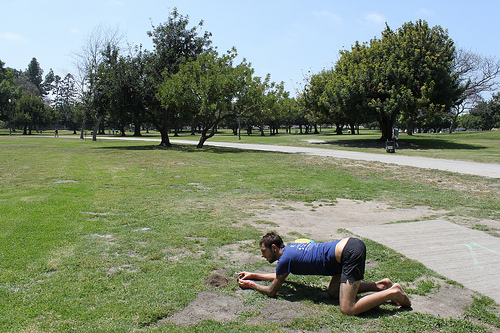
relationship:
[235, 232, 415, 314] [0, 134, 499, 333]
man on grass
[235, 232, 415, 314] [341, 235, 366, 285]
man wearing shorts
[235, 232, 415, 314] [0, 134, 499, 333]
man looking at grass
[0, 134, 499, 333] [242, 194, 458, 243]
grass has spot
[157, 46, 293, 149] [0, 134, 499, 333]
tree on grass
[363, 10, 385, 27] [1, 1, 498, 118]
cloud in sky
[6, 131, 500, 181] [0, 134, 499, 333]
pathway next to grass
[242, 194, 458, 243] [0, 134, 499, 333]
spot in grass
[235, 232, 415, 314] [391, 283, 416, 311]
man has foot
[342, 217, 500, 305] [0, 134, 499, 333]
walkway in grass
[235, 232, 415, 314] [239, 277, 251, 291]
man has hand